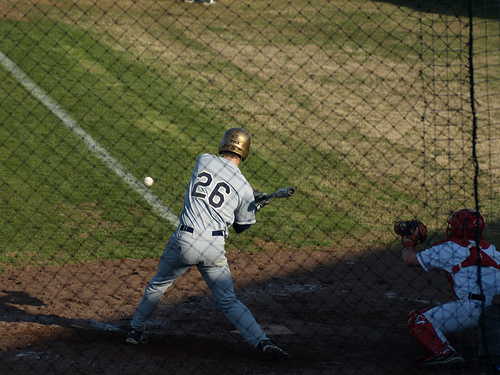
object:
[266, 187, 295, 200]
bat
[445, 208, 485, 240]
catcher's mask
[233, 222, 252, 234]
elbow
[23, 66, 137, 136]
color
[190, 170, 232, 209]
26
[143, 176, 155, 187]
ball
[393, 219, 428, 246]
glove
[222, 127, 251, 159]
head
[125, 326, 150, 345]
foot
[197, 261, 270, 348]
leg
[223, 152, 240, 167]
neck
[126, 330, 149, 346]
shoes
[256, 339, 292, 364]
shoes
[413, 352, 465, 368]
shoes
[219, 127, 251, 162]
helmet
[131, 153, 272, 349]
uniform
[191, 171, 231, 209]
number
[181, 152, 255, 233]
jersey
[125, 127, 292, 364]
ball player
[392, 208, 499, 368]
catcher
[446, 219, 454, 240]
face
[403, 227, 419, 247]
hand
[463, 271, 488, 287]
white (clothes)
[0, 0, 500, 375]
netting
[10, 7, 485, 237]
air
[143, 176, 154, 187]
pitch